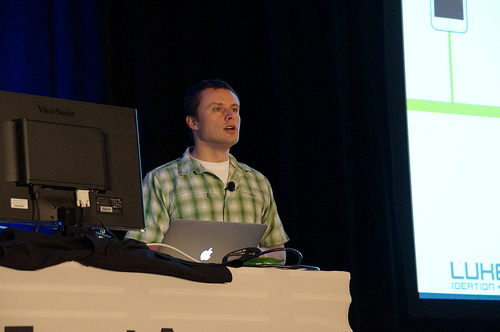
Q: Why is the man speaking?
A: Presenation.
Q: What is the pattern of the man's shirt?
A: Plaid.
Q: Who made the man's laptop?
A: Apple.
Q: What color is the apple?
A: White.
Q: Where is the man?
A: College.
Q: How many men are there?
A: One.